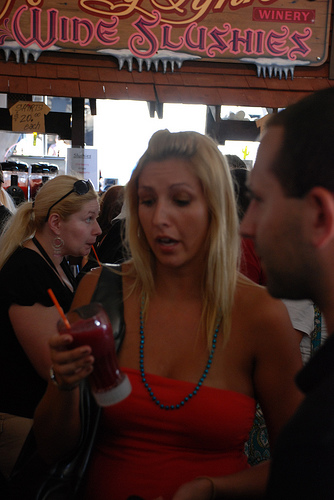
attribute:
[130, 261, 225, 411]
necklace — blue, beaded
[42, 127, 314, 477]
woman — blonde, looking, drinking, open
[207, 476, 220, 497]
bracelet — silver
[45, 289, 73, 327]
straw — orange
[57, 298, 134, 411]
cup — frozen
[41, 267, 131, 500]
purse — silver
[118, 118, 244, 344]
hair — blond, blonde, long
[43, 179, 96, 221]
sunglasses — dark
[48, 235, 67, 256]
earring — silver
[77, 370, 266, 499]
top — orange, red, pink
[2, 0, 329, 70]
sign — slushy, hanging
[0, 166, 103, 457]
lady — drinking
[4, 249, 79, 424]
blouse — black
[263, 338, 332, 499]
shirt — black, yellow